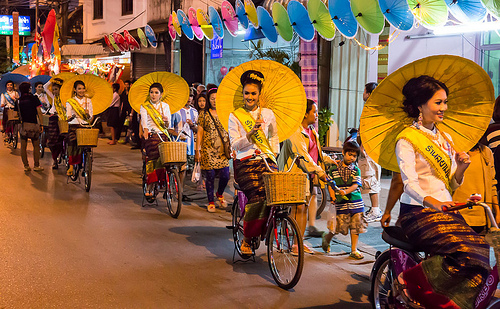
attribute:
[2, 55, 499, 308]
women — asian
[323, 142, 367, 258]
boy — little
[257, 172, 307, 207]
basket — tan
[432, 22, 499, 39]
light — fluorescent, flruorescent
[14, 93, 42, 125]
shirt — black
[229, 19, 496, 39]
lights — decorative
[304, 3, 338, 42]
umbrella — green, hanging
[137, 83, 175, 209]
girl — third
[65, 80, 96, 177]
girl — fourth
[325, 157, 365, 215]
shirt — green, striped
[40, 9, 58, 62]
umbrella — red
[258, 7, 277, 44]
umbrella — blue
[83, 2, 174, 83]
building — white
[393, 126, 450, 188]
sash — yellow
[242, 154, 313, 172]
handles — silver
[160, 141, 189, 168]
basket — woven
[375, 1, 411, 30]
umbrella — blue